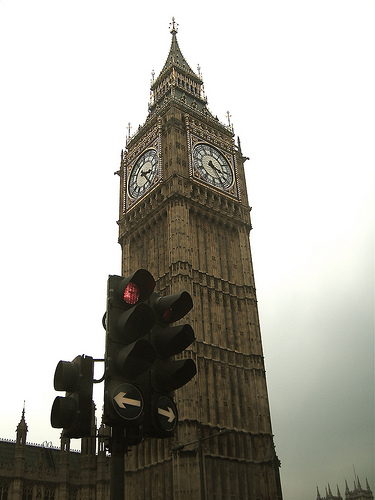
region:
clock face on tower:
[192, 134, 241, 192]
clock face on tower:
[112, 145, 167, 202]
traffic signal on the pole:
[110, 268, 159, 383]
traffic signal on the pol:
[156, 288, 204, 392]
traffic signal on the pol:
[43, 353, 97, 437]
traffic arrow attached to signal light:
[109, 385, 149, 424]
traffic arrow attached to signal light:
[150, 396, 179, 434]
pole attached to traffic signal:
[110, 453, 136, 498]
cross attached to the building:
[118, 118, 137, 132]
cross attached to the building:
[220, 104, 231, 120]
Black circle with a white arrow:
[109, 382, 145, 420]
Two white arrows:
[112, 390, 176, 426]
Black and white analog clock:
[190, 140, 235, 189]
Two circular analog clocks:
[124, 138, 234, 196]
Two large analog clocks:
[125, 141, 235, 204]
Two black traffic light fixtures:
[105, 265, 199, 397]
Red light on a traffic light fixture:
[120, 265, 153, 307]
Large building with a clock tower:
[0, 13, 287, 498]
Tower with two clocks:
[109, 10, 283, 499]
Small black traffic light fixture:
[46, 352, 97, 440]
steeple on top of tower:
[147, 13, 206, 82]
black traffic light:
[38, 346, 104, 449]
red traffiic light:
[100, 262, 160, 308]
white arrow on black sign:
[112, 381, 179, 427]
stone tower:
[100, 17, 284, 498]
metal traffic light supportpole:
[105, 443, 133, 498]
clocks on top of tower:
[188, 132, 238, 192]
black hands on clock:
[205, 153, 231, 190]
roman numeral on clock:
[199, 144, 217, 159]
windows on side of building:
[25, 483, 57, 498]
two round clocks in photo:
[103, 122, 246, 219]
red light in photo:
[84, 263, 171, 334]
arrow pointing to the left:
[91, 373, 157, 422]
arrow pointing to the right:
[148, 387, 188, 435]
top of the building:
[142, 5, 217, 72]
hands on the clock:
[204, 154, 224, 176]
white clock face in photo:
[179, 145, 239, 188]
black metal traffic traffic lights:
[108, 272, 197, 430]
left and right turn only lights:
[101, 376, 177, 436]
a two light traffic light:
[45, 354, 95, 437]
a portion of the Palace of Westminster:
[1, 401, 97, 496]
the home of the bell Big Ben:
[143, 37, 207, 100]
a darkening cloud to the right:
[280, 240, 368, 482]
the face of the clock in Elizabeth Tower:
[191, 137, 244, 191]